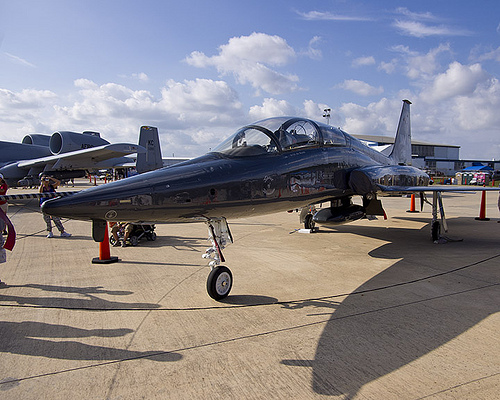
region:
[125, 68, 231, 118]
Section of the sky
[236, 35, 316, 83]
Section of the sky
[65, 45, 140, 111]
Section of the sky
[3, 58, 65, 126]
Section of the sky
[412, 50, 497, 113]
Section of the sky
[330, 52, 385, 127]
Section of the sky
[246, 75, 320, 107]
Section of the sky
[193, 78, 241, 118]
Section of the sky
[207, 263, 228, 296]
a tire on the plane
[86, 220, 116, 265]
an orange traffic cone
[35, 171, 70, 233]
a person taking a picture of the plane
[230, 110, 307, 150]
the windshield on the plane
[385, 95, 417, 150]
the tail wing on the plane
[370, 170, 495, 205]
the wing on the plane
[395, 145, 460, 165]
a white building behind the plane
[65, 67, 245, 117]
clouds in the sky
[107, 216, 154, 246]
a kid in a stroller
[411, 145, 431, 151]
windows of the building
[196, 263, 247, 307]
black wheel on aircraft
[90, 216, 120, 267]
red safety cone behind aircraft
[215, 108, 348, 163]
cockpit on silver aircraft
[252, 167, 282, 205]
decal on side of aircraft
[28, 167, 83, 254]
person standing behind aircraft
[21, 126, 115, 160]
large jet engine on aircraft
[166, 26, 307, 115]
large white clouds in sky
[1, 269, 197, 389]
shadow of people on runway concrete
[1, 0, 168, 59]
clear blue cloudless sky above airport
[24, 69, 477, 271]
this is a plane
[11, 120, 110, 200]
this is a plane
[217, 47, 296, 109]
this is a cloud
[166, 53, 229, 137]
this is a cloud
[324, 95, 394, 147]
this is a cloud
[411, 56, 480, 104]
this is a cloud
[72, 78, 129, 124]
this is a cloud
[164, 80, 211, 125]
this is a cloud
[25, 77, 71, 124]
this is a cloud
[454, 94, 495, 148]
this is a cloud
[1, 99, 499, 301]
the airplanes are parked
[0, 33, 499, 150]
fluffy white clouds in sky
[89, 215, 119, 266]
orange traffic cone on tarmac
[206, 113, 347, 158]
clear cockpit of jet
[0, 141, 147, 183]
left wing of plane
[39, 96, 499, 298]
jet is silver grey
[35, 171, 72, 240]
person standing next to jet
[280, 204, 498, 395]
shadow of jet on ground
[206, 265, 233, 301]
wheel is white with black tire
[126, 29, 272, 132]
blue and white sky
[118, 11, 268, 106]
white clouds in sky